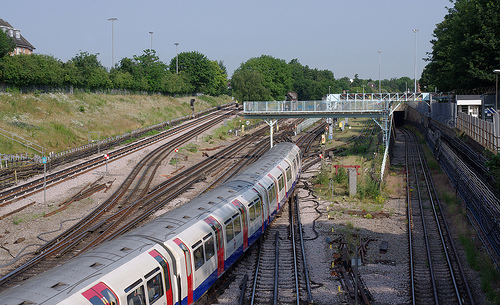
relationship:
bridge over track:
[244, 99, 393, 147] [402, 131, 469, 303]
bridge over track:
[244, 99, 393, 147] [236, 183, 308, 303]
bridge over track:
[244, 99, 393, 147] [293, 118, 328, 158]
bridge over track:
[244, 99, 393, 147] [0, 115, 301, 280]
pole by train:
[348, 168, 361, 198] [7, 138, 316, 304]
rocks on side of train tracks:
[296, 226, 373, 302] [232, 218, 399, 282]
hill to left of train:
[2, 80, 238, 194] [7, 138, 316, 304]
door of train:
[203, 216, 225, 277] [7, 138, 316, 304]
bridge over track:
[244, 99, 396, 142] [402, 131, 469, 303]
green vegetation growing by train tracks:
[313, 163, 389, 219] [0, 105, 477, 304]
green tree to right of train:
[441, 23, 483, 67] [425, 79, 496, 144]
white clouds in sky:
[265, 14, 329, 41] [5, 1, 468, 95]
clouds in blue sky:
[358, 16, 398, 59] [2, 0, 454, 80]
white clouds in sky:
[265, 14, 329, 41] [8, 2, 465, 78]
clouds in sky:
[0, 0, 426, 59] [8, 2, 465, 78]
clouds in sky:
[0, 0, 426, 59] [323, 20, 415, 68]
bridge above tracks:
[244, 99, 393, 147] [234, 111, 478, 302]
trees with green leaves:
[42, 52, 173, 88] [56, 59, 106, 85]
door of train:
[209, 226, 227, 266] [133, 180, 284, 284]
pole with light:
[168, 25, 186, 78] [167, 36, 185, 51]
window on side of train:
[189, 241, 206, 269] [7, 138, 316, 304]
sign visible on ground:
[34, 150, 55, 171] [1, 89, 499, 303]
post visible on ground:
[37, 163, 59, 214] [1, 89, 499, 303]